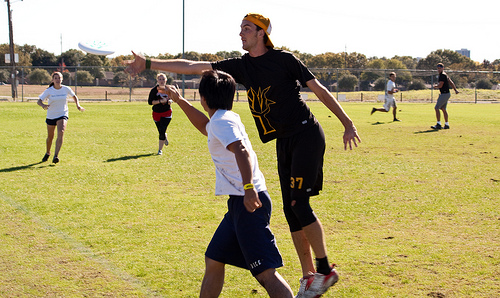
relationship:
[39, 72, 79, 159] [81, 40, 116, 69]
girl playing frisbee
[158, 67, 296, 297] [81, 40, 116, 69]
boy playing frisbee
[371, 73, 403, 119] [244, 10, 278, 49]
man in hat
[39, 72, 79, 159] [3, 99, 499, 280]
woman in field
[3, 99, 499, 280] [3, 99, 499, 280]
grass on field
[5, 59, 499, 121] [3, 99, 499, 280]
fence separating field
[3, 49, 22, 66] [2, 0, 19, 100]
transformer on utility pole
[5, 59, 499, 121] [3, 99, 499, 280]
fence bordering field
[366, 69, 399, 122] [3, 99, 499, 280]
person on grass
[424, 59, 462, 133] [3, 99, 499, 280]
person on grass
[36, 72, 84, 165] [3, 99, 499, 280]
girl on grass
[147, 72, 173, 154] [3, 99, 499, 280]
person on grass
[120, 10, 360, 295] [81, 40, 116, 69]
man reaching for frisbee